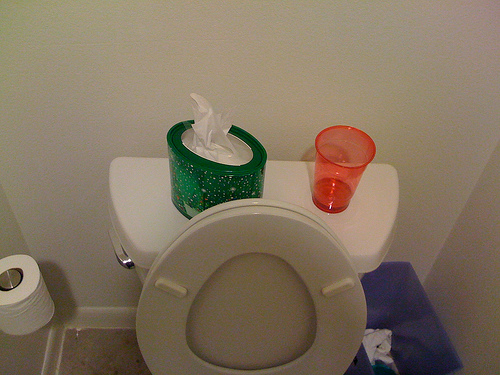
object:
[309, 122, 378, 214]
cup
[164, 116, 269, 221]
dispenser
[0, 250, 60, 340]
toilet paper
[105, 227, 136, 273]
level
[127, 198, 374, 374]
seat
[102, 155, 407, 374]
toilet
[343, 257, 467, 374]
waste basket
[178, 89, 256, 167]
tissue paper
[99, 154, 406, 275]
lid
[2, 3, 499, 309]
wall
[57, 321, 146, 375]
floor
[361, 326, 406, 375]
trash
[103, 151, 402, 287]
tank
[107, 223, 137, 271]
lever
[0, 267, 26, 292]
roll holder